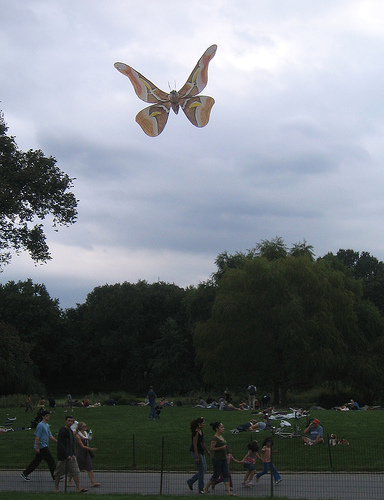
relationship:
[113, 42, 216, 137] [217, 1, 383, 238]
kite in sky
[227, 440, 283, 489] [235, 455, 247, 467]
girls holding hands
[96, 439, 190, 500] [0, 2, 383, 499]
fence in park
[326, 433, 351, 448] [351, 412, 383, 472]
dog in grass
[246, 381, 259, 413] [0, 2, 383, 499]
people in park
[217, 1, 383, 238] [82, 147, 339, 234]
sky has clouds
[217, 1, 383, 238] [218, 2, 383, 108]
clouds dont block sun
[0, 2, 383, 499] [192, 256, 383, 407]
park has shady trees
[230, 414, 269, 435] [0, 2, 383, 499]
people in park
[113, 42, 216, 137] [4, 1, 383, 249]
kite in flight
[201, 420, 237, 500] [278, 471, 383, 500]
people on park path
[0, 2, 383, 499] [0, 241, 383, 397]
park has trees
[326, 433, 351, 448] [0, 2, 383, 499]
dog in park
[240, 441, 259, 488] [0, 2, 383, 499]
kids in park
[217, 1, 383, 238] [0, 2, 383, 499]
cloudy sky over park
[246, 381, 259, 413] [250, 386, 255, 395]
man has a backpack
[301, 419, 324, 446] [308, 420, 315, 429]
man on a cellphone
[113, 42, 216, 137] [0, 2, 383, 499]
butterfly kite in park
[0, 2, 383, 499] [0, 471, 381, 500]
park has a walkway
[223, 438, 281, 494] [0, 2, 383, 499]
children playing in park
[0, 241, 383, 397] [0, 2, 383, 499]
trees in park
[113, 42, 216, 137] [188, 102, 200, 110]
kite has yellow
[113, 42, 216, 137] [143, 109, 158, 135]
kite has white color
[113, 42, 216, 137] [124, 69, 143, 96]
kite has an orange color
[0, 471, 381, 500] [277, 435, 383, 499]
park path has a fence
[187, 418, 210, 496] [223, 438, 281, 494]
two women with children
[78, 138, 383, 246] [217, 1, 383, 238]
clouds in sky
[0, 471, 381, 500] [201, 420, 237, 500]
sidewalk full of people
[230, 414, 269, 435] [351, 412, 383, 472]
people in grass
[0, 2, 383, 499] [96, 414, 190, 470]
park has green grass